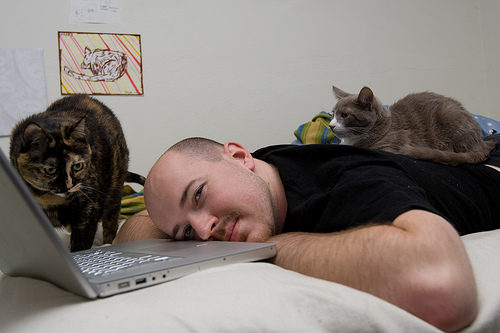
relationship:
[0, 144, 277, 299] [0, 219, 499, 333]
laptop on bed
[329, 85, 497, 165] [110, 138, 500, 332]
cat on man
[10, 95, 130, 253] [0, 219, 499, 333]
cat on bed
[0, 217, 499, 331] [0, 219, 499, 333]
comforter on bed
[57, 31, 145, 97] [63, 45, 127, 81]
picture of cat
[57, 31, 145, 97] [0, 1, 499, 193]
picture on wall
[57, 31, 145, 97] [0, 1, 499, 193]
pictures on wall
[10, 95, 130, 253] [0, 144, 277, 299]
cat looking laptop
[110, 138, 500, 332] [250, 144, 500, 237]
man wearing shirt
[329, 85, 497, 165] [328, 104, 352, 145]
cat has white face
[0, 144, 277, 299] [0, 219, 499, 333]
computer on bed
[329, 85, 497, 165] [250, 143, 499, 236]
cat on back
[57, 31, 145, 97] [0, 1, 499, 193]
drawing hanging wall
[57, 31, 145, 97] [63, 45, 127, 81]
drawing of cat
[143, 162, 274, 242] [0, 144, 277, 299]
face on laptop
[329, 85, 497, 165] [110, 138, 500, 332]
cat with man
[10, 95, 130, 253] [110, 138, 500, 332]
cat with man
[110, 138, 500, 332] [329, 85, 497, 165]
man with cat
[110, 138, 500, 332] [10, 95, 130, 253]
man with cat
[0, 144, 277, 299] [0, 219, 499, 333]
laptop on pillow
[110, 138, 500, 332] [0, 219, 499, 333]
man on bed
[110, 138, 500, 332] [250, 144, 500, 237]
man wearing black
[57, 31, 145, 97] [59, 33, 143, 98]
picture with stripes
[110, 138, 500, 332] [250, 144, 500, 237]
man in black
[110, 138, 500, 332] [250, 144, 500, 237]
man in shirt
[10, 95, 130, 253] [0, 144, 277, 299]
cat near laptop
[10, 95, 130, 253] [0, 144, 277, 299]
cat next to laptop